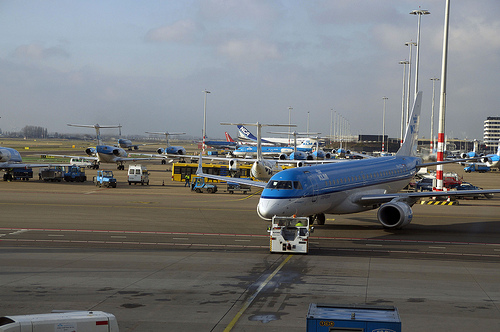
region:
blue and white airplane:
[188, 83, 496, 263]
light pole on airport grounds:
[430, 3, 455, 204]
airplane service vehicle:
[262, 203, 322, 248]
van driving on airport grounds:
[122, 152, 149, 192]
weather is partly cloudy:
[0, 1, 495, 143]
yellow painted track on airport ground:
[204, 223, 312, 325]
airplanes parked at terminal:
[197, 119, 319, 163]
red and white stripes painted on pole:
[432, 132, 447, 202]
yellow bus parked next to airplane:
[168, 155, 273, 182]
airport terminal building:
[327, 135, 417, 149]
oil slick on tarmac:
[232, 248, 319, 286]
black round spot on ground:
[113, 281, 172, 310]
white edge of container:
[308, 298, 412, 325]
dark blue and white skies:
[201, 40, 335, 77]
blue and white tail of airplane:
[233, 115, 265, 152]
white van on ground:
[116, 154, 163, 190]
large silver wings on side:
[368, 195, 463, 247]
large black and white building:
[478, 109, 496, 151]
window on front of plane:
[247, 164, 315, 199]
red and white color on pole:
[430, 127, 462, 224]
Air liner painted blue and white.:
[174, 100, 477, 265]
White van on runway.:
[123, 157, 154, 183]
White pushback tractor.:
[261, 209, 316, 262]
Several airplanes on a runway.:
[66, 87, 495, 260]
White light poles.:
[377, 1, 482, 209]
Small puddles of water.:
[210, 235, 328, 330]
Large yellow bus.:
[165, 162, 261, 190]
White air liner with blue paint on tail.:
[236, 121, 321, 153]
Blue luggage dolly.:
[181, 175, 260, 195]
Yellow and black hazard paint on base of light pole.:
[423, 197, 460, 209]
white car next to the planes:
[122, 158, 162, 199]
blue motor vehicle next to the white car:
[87, 168, 121, 195]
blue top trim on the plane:
[236, 142, 441, 197]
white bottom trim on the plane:
[241, 174, 476, 228]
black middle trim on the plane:
[259, 166, 425, 200]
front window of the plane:
[264, 177, 312, 197]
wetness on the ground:
[212, 246, 331, 328]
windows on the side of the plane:
[304, 162, 420, 184]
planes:
[173, 111, 329, 170]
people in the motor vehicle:
[270, 213, 316, 238]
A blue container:
[305, 298, 403, 329]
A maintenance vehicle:
[265, 210, 311, 254]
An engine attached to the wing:
[360, 188, 498, 229]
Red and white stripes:
[434, 129, 451, 160]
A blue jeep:
[96, 168, 118, 186]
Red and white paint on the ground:
[24, 223, 156, 234]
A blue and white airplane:
[258, 155, 422, 211]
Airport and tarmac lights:
[197, 88, 352, 118]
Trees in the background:
[13, 124, 53, 138]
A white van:
[124, 164, 153, 186]